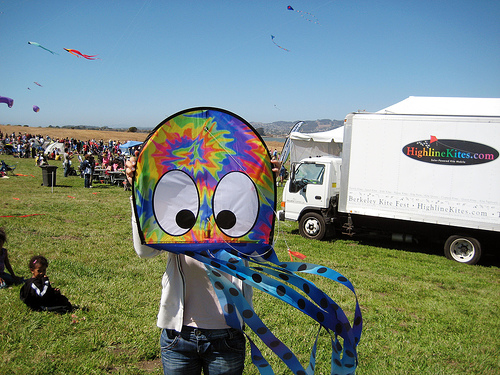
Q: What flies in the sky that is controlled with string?
A: Kites.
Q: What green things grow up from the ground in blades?
A: Grass.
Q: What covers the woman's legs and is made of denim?
A: Jeans.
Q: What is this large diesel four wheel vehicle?
A: Truck.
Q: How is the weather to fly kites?
A: Windy.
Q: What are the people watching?
A: Kites.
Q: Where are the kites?
A: Flying through the air.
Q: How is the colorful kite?
A: Rainbow colored.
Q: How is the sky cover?
A: The sky is clear and blue.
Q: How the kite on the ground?
A: Multi-colored kite with big eyes.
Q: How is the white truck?
A: Truck with kite company logo on it.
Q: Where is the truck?
A: On the grass.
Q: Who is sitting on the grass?
A: A child.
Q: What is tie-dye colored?
A: A kite.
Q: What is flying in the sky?
A: Kites.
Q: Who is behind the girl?
A: A crowd of people.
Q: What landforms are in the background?
A: Mountains.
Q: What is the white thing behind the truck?
A: A tent.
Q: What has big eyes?
A: The kite.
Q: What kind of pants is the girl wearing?
A: Jeans.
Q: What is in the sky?
A: Kites.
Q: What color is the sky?
A: Blue.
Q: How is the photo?
A: Clear.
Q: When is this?
A: Daytime.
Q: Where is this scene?
A: A field.